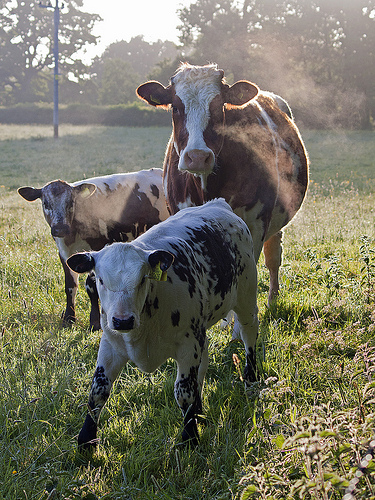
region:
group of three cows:
[43, 40, 336, 460]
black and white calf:
[68, 249, 276, 452]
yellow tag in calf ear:
[156, 265, 174, 286]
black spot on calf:
[170, 311, 185, 327]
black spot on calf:
[189, 287, 198, 296]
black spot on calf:
[98, 378, 107, 386]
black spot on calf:
[191, 351, 196, 363]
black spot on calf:
[192, 343, 201, 352]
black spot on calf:
[178, 329, 191, 341]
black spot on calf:
[227, 284, 240, 302]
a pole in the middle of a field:
[31, 1, 82, 140]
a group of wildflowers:
[237, 240, 374, 498]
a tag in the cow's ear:
[148, 255, 168, 285]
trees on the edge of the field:
[0, 0, 374, 131]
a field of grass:
[0, 122, 373, 499]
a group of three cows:
[10, 53, 315, 459]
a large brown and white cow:
[127, 59, 311, 311]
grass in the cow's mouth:
[174, 149, 221, 182]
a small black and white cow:
[58, 196, 272, 463]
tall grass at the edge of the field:
[0, 105, 176, 129]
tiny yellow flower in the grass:
[8, 468, 17, 477]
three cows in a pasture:
[31, 60, 314, 380]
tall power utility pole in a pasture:
[29, 1, 67, 140]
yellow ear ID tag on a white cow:
[148, 257, 169, 284]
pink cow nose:
[182, 150, 213, 172]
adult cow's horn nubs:
[165, 67, 226, 78]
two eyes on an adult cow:
[168, 100, 225, 118]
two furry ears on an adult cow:
[129, 78, 261, 110]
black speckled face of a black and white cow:
[16, 176, 96, 238]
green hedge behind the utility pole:
[0, 97, 175, 129]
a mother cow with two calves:
[13, 61, 316, 461]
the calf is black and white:
[56, 197, 261, 461]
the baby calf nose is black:
[110, 313, 136, 334]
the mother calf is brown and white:
[138, 60, 311, 316]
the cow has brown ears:
[129, 73, 259, 115]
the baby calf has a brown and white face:
[19, 176, 96, 240]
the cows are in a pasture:
[5, 104, 371, 489]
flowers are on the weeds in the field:
[256, 372, 371, 494]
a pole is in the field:
[40, 0, 70, 141]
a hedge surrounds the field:
[3, 99, 373, 130]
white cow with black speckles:
[53, 198, 299, 461]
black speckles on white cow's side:
[147, 218, 250, 304]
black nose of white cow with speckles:
[109, 313, 136, 333]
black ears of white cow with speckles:
[60, 241, 177, 274]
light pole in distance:
[41, 2, 71, 138]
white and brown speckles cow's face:
[16, 178, 95, 243]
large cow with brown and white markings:
[141, 59, 323, 304]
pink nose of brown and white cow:
[178, 146, 215, 178]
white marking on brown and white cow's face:
[171, 63, 221, 159]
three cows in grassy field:
[11, 50, 313, 491]